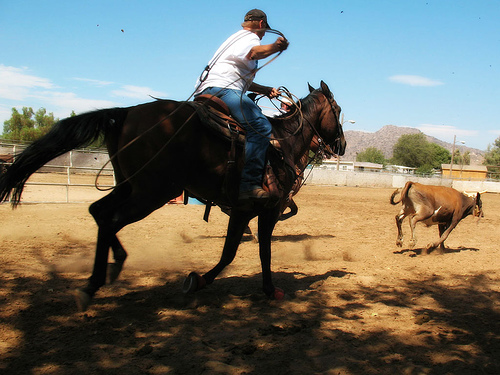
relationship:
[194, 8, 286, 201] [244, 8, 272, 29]
man has a cap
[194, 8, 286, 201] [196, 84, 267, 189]
man wearing jeans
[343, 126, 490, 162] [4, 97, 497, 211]
hill in background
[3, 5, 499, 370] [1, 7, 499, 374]
man on a horse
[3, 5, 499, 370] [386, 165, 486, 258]
man chasing a cow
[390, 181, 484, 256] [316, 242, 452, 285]
cow running in dirt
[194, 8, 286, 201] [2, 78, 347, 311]
man riding on horse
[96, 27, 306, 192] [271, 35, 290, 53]
lasso in right hand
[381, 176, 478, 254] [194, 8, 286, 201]
cow running from man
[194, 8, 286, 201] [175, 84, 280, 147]
man on horseback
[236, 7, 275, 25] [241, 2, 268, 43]
cap on head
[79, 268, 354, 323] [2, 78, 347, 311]
shadow of horse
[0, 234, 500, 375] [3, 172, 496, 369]
shadow on ground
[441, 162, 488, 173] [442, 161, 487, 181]
gray roof on brown building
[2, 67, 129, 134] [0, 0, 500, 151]
clouds in blue sky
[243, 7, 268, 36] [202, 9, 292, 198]
head of man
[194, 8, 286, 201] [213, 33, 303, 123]
man has lasso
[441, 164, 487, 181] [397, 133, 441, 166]
brown building beside trees